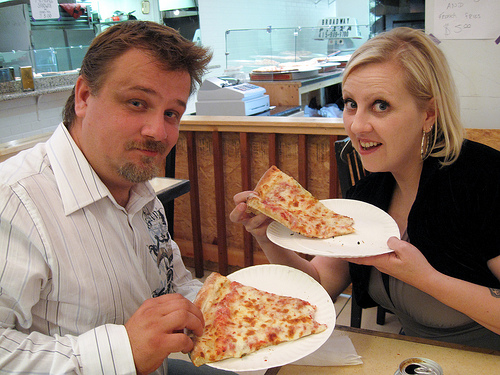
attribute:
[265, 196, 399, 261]
plate — white, paper, round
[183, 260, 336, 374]
plate — white, paper, round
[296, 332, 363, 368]
napkin — white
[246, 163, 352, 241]
pizza slice — triangular, cheese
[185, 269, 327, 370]
pizza slice — cheese, triangular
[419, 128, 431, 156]
earring — silver, hoop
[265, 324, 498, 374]
table — light colored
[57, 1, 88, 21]
pizza bag — red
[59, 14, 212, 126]
hair — short, dark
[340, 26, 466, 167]
hair — blonde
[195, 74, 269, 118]
cash register — white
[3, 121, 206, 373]
shirt — striped, button up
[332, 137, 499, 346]
shirt — black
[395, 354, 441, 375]
soda can — open